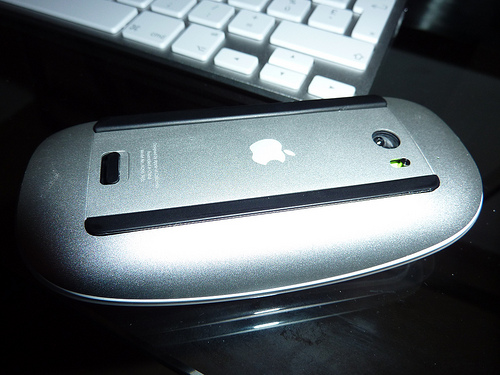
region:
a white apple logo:
[236, 120, 303, 174]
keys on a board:
[142, 10, 391, 55]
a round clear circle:
[371, 113, 401, 156]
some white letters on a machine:
[137, 139, 161, 189]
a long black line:
[53, 173, 452, 220]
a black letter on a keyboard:
[271, 70, 289, 77]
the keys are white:
[172, 14, 333, 96]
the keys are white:
[182, 5, 382, 85]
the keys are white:
[199, 5, 356, 102]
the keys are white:
[187, 11, 377, 79]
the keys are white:
[197, 12, 385, 96]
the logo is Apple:
[244, 125, 299, 175]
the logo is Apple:
[235, 125, 292, 175]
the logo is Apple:
[240, 125, 295, 170]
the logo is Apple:
[239, 129, 296, 176]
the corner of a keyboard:
[15, 8, 376, 103]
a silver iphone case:
[18, 93, 480, 311]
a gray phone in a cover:
[8, 90, 482, 314]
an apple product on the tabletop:
[15, 88, 483, 325]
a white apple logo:
[240, 133, 302, 173]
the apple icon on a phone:
[240, 130, 304, 174]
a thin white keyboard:
[4, 0, 409, 98]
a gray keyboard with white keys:
[2, 0, 417, 102]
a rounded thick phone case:
[12, 90, 487, 324]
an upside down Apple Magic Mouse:
[11, 92, 486, 309]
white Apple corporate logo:
[246, 136, 293, 167]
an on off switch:
[389, 157, 410, 170]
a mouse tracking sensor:
[371, 128, 400, 151]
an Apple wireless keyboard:
[0, 0, 404, 115]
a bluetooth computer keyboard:
[2, 0, 409, 109]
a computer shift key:
[270, 21, 372, 71]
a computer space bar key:
[4, 0, 139, 38]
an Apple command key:
[121, 10, 185, 52]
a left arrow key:
[214, 46, 257, 75]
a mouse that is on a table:
[72, 65, 484, 350]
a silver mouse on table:
[28, 88, 493, 365]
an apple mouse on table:
[39, 123, 476, 337]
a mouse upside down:
[44, 104, 460, 343]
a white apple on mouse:
[214, 138, 293, 162]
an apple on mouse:
[251, 131, 293, 166]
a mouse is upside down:
[87, 130, 436, 358]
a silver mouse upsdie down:
[47, 98, 425, 337]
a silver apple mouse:
[104, 80, 453, 315]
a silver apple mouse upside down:
[28, 77, 453, 347]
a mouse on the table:
[53, 70, 431, 275]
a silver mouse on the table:
[34, 88, 457, 323]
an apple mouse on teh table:
[75, 92, 449, 300]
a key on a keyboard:
[272, 7, 371, 74]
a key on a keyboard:
[250, 57, 305, 97]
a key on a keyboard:
[268, 40, 305, 70]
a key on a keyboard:
[215, 43, 263, 74]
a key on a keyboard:
[125, 5, 170, 58]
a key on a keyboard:
[187, 0, 223, 25]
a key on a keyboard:
[10, 0, 139, 36]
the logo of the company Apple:
[234, 128, 304, 179]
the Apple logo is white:
[238, 128, 301, 172]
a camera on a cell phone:
[364, 117, 405, 156]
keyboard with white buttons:
[13, 1, 412, 118]